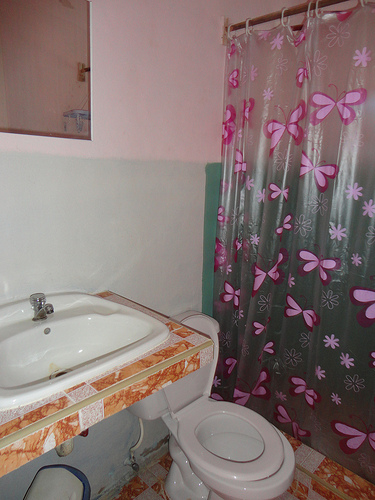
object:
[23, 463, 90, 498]
trash can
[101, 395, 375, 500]
floor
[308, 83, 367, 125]
black cat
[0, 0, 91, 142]
mirror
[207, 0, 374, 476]
shower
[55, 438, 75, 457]
pipe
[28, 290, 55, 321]
faucet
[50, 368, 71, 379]
drain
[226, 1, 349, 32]
shower rod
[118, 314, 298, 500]
toilet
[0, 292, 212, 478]
counter top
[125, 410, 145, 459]
pipe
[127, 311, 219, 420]
toilet tank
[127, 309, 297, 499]
toilet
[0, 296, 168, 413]
sink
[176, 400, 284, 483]
seat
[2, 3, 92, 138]
panel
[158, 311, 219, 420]
lid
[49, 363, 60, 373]
stain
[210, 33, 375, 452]
butterfly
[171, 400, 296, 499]
stool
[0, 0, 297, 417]
wall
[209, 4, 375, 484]
curtain